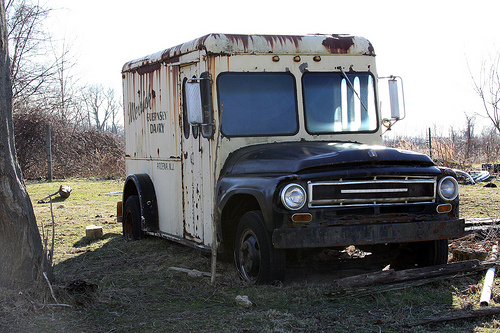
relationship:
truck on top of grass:
[118, 31, 465, 285] [0, 179, 499, 333]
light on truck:
[283, 184, 309, 212] [118, 31, 465, 285]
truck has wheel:
[118, 31, 465, 285] [124, 197, 141, 242]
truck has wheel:
[118, 31, 465, 285] [235, 212, 289, 290]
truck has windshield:
[118, 31, 465, 285] [217, 73, 380, 138]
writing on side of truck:
[127, 89, 168, 133] [118, 31, 465, 285]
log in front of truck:
[234, 259, 480, 309] [118, 31, 465, 285]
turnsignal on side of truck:
[292, 212, 313, 224] [118, 31, 465, 285]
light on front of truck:
[283, 184, 309, 212] [118, 31, 465, 285]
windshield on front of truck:
[217, 73, 380, 138] [118, 31, 465, 285]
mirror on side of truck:
[389, 77, 406, 122] [118, 31, 465, 285]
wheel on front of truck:
[414, 242, 448, 265] [118, 31, 465, 285]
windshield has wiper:
[217, 73, 380, 138] [336, 67, 373, 121]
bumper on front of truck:
[272, 218, 468, 250] [118, 31, 465, 285]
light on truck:
[442, 179, 459, 199] [118, 31, 465, 285]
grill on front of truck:
[306, 176, 447, 216] [118, 31, 465, 285]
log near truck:
[234, 259, 480, 309] [118, 31, 465, 285]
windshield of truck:
[217, 73, 380, 138] [118, 31, 465, 285]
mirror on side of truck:
[186, 76, 205, 128] [118, 31, 465, 285]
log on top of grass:
[234, 259, 480, 309] [0, 179, 499, 333]